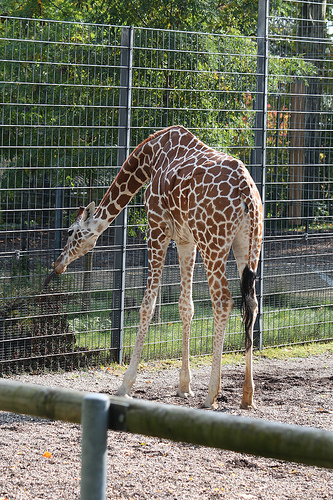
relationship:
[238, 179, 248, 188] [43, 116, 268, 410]
spot on giraffe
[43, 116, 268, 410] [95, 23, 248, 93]
giraffe eating through fence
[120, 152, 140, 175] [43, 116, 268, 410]
spot on giraffe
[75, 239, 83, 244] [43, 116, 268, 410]
spot on giraffe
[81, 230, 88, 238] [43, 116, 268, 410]
spot on giraffe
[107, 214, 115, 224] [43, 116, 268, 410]
spot on giraffe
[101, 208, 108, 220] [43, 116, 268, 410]
spot on giraffe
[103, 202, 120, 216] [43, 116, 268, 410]
spot on giraffe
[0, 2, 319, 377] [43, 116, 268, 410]
fence behind giraffe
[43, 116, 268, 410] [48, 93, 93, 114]
giraffe eating leaves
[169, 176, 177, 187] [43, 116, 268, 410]
spot on giraffe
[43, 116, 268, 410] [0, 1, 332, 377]
giraffe eating in pen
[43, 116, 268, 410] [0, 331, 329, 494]
giraffe standing in ground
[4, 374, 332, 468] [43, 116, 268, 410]
pole behind giraffe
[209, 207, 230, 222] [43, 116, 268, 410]
spot on a giraffe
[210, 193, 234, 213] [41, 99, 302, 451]
spot on a giraffe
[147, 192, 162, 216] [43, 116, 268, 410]
spot on a giraffe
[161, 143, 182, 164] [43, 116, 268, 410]
spot on a giraffe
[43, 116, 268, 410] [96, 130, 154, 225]
giraffe behind h neck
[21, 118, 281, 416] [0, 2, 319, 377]
giraffe by fence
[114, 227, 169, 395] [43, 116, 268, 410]
legs on giraffe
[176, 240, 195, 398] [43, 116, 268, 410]
legs on giraffe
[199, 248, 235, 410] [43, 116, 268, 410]
legs on giraffe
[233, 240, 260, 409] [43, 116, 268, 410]
legs on giraffe